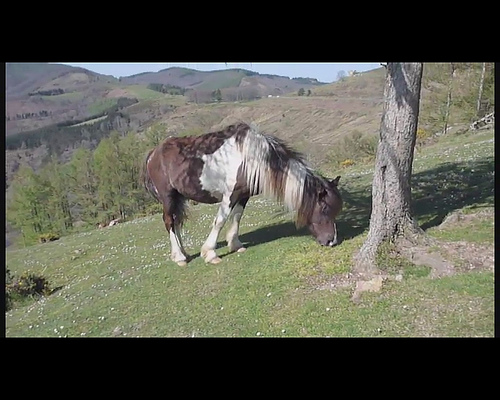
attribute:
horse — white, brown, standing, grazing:
[144, 121, 343, 265]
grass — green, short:
[1, 133, 499, 339]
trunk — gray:
[360, 62, 433, 264]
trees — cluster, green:
[147, 83, 188, 96]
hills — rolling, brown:
[4, 63, 328, 144]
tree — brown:
[352, 61, 431, 270]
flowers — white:
[101, 236, 154, 285]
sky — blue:
[56, 63, 384, 82]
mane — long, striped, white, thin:
[244, 124, 328, 232]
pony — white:
[144, 123, 341, 270]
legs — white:
[202, 197, 249, 263]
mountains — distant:
[118, 67, 328, 102]